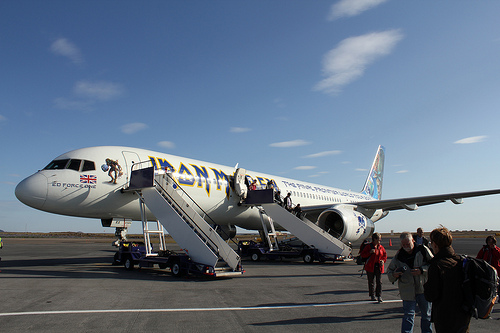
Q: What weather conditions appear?
A: It is clear.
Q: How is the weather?
A: It is clear.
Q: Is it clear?
A: Yes, it is clear.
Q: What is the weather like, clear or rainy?
A: It is clear.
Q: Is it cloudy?
A: No, it is clear.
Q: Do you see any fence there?
A: No, there are no fences.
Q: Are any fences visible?
A: No, there are no fences.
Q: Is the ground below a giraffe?
A: No, the ground is below an airplane.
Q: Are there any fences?
A: No, there are no fences.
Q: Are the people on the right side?
A: Yes, the people are on the right of the image.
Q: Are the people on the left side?
A: No, the people are on the right of the image.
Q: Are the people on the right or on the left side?
A: The people are on the right of the image.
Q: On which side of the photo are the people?
A: The people are on the right of the image.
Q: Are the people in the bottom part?
A: Yes, the people are in the bottom of the image.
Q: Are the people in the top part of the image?
A: No, the people are in the bottom of the image.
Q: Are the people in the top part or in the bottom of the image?
A: The people are in the bottom of the image.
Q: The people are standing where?
A: The people are standing on the road.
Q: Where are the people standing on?
A: The people are standing on the road.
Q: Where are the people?
A: The people are on the road.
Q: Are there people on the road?
A: Yes, there are people on the road.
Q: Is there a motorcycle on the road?
A: No, there are people on the road.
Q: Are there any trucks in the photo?
A: No, there are no trucks.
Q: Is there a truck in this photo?
A: No, there are no trucks.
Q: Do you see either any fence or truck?
A: No, there are no trucks or fences.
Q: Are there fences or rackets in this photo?
A: No, there are no fences or rackets.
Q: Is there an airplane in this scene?
A: Yes, there is an airplane.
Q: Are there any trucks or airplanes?
A: Yes, there is an airplane.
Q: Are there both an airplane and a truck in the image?
A: No, there is an airplane but no trucks.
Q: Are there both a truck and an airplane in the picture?
A: No, there is an airplane but no trucks.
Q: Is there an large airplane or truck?
A: Yes, there is a large airplane.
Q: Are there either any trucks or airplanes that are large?
A: Yes, the airplane is large.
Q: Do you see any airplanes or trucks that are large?
A: Yes, the airplane is large.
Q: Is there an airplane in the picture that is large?
A: Yes, there is a large airplane.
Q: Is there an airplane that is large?
A: Yes, there is an airplane that is large.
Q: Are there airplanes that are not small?
A: Yes, there is a large airplane.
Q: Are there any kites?
A: No, there are no kites.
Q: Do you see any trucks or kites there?
A: No, there are no kites or trucks.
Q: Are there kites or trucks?
A: No, there are no kites or trucks.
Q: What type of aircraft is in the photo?
A: The aircraft is an airplane.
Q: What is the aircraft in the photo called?
A: The aircraft is an airplane.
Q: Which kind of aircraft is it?
A: The aircraft is an airplane.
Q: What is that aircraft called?
A: This is an airplane.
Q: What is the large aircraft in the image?
A: The aircraft is an airplane.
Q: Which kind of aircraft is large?
A: The aircraft is an airplane.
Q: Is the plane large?
A: Yes, the plane is large.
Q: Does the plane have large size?
A: Yes, the plane is large.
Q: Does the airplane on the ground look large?
A: Yes, the plane is large.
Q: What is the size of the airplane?
A: The airplane is large.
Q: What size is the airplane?
A: The airplane is large.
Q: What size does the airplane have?
A: The airplane has large size.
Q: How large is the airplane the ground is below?
A: The airplane is large.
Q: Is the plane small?
A: No, the plane is large.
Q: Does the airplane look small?
A: No, the airplane is large.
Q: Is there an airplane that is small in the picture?
A: No, there is an airplane but it is large.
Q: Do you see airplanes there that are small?
A: No, there is an airplane but it is large.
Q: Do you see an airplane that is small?
A: No, there is an airplane but it is large.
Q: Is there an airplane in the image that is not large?
A: No, there is an airplane but it is large.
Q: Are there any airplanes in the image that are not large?
A: No, there is an airplane but it is large.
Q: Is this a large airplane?
A: Yes, this is a large airplane.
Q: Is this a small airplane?
A: No, this is a large airplane.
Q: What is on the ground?
A: The airplane is on the ground.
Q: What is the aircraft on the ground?
A: The aircraft is an airplane.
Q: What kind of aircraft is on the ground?
A: The aircraft is an airplane.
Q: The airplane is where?
A: The airplane is on the ground.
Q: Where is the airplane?
A: The airplane is on the ground.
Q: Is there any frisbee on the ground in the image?
A: No, there is an airplane on the ground.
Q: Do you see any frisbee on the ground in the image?
A: No, there is an airplane on the ground.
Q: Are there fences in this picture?
A: No, there are no fences.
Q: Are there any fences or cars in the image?
A: No, there are no fences or cars.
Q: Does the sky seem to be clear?
A: Yes, the sky is clear.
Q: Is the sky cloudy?
A: No, the sky is clear.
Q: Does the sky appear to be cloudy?
A: No, the sky is clear.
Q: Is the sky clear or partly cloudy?
A: The sky is clear.